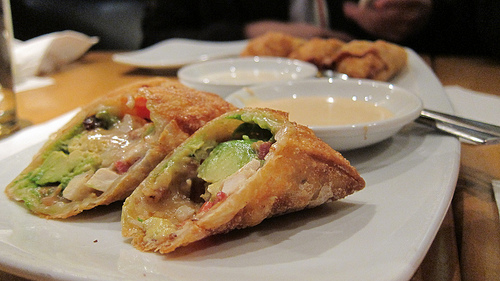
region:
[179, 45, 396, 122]
two bowls of dipping sauce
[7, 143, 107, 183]
piece of avacado in a shell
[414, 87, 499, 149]
handle of eating utensil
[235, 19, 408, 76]
fried pieces of wrapped food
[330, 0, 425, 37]
a person looking down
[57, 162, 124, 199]
bits of chicken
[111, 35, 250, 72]
a square china plate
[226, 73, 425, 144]
a shallow china bowl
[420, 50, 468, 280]
two tables put together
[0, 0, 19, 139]
edge of a filled water glass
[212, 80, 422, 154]
White bowl on plate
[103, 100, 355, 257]
Fried bread with vegetables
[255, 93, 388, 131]
Brown condiment sauce in bowl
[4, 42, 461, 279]
Oval white plate with food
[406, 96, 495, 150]
Metal utensils on plate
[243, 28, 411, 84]
Fried food items on back of plate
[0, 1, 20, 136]
Clear beverage glass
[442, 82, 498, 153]
White napkin on table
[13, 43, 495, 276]
Wooden table top with plates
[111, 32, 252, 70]
Empty square plate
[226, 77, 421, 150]
a bowl of dip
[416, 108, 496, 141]
the handle of a utensil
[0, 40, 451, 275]
a large rounded rectangular plate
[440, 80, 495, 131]
a white napkin under a plate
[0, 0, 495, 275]
a wooden table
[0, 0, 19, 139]
a glass on a table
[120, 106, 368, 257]
a fried sandwich half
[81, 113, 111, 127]
a black olive in a sandwich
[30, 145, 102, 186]
a yellow green avocado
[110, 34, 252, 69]
an empty white plate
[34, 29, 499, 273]
food on a plate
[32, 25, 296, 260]
food on a white plate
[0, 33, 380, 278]
a plate of food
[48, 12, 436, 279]
a white plate of food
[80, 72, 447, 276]
food on a table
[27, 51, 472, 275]
food on a brown table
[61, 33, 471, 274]
prepared food on plate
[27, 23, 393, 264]
plate with prepared food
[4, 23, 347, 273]
white plate with food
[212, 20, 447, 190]
bowls of sauce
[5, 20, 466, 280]
a dish shaped triangular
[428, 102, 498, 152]
the handle of utensil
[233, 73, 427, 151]
a white bowl with sauce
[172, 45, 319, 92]
a white bowl with sauce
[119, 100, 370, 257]
a cone with salad of vegetables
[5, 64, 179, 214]
a cone with salad of vegetables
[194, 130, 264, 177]
a spice of avocado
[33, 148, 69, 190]
a spice of avocado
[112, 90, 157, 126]
a slice of tomato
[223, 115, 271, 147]
a slice of olives